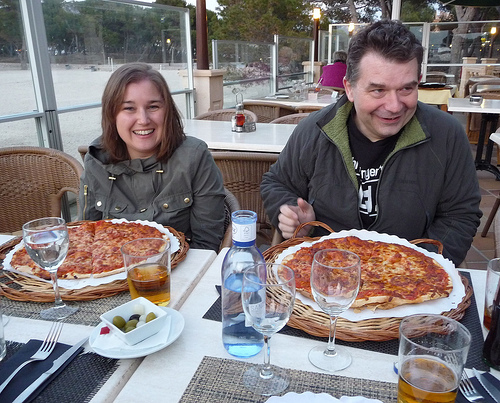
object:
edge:
[252, 282, 273, 287]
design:
[350, 157, 384, 218]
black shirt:
[347, 107, 402, 230]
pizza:
[9, 220, 169, 280]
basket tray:
[1, 217, 181, 290]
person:
[318, 50, 347, 89]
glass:
[395, 313, 473, 403]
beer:
[395, 355, 461, 403]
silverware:
[457, 368, 482, 403]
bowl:
[100, 296, 167, 346]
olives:
[146, 312, 157, 323]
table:
[0, 230, 497, 403]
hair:
[99, 62, 188, 165]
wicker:
[18, 151, 40, 223]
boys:
[22, 216, 80, 321]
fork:
[0, 321, 62, 394]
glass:
[120, 237, 171, 307]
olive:
[113, 315, 126, 327]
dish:
[89, 306, 184, 361]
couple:
[79, 19, 482, 270]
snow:
[0, 63, 94, 118]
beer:
[126, 263, 170, 307]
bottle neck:
[231, 210, 258, 247]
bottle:
[220, 209, 266, 356]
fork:
[11, 337, 91, 403]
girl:
[75, 62, 225, 253]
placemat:
[173, 354, 401, 403]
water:
[23, 232, 67, 272]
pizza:
[276, 236, 453, 311]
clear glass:
[240, 264, 295, 394]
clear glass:
[308, 248, 361, 372]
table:
[77, 116, 301, 150]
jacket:
[76, 134, 228, 252]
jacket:
[318, 62, 348, 88]